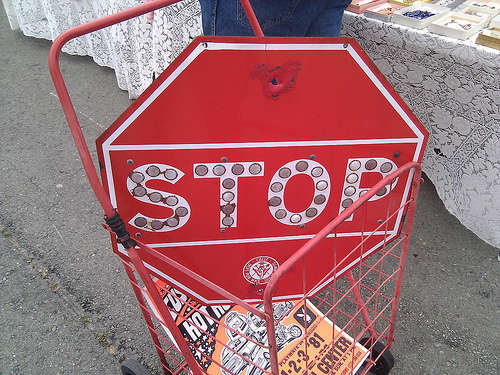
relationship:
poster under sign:
[141, 276, 371, 374] [93, 36, 430, 306]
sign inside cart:
[93, 36, 430, 306] [50, 1, 426, 374]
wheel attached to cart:
[359, 337, 395, 373] [50, 1, 426, 374]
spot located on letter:
[145, 166, 161, 177] [126, 164, 192, 234]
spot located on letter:
[132, 186, 146, 197] [126, 164, 192, 234]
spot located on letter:
[166, 196, 177, 207] [126, 164, 192, 234]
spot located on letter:
[135, 217, 146, 225] [126, 164, 192, 234]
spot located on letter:
[151, 219, 163, 230] [126, 164, 192, 234]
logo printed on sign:
[243, 254, 279, 287] [93, 36, 430, 306]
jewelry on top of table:
[350, 1, 500, 50] [340, 1, 499, 250]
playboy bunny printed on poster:
[294, 303, 317, 329] [141, 276, 371, 374]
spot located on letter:
[270, 182, 282, 193] [267, 159, 332, 225]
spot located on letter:
[291, 214, 300, 223] [267, 159, 332, 225]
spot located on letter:
[315, 195, 326, 204] [267, 159, 332, 225]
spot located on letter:
[318, 180, 328, 188] [267, 159, 332, 225]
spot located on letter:
[297, 159, 308, 172] [267, 159, 332, 225]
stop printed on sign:
[124, 159, 399, 232] [93, 36, 430, 306]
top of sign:
[96, 39, 427, 145] [93, 36, 430, 306]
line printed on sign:
[106, 137, 419, 152] [93, 36, 430, 306]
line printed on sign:
[133, 231, 394, 246] [93, 36, 430, 306]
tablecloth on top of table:
[342, 11, 500, 250] [340, 1, 499, 250]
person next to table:
[200, 1, 353, 40] [340, 1, 499, 250]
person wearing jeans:
[200, 1, 353, 40] [197, 1, 352, 38]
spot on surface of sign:
[214, 165, 226, 176] [93, 36, 430, 306]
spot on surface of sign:
[348, 171, 358, 184] [93, 36, 430, 306]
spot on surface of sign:
[270, 195, 281, 206] [93, 36, 430, 306]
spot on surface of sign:
[381, 161, 393, 173] [93, 36, 430, 306]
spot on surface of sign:
[223, 216, 230, 223] [93, 36, 430, 306]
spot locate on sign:
[348, 171, 358, 184] [93, 36, 430, 306]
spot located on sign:
[194, 165, 208, 178] [93, 36, 430, 306]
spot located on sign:
[249, 164, 260, 172] [93, 36, 430, 306]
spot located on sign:
[278, 165, 291, 180] [93, 36, 430, 306]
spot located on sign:
[132, 186, 146, 197] [93, 36, 430, 306]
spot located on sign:
[166, 196, 177, 207] [93, 36, 430, 306]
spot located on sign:
[312, 166, 321, 178] [93, 36, 430, 306]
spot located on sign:
[291, 214, 300, 223] [93, 36, 430, 306]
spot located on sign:
[270, 182, 282, 193] [93, 36, 430, 306]